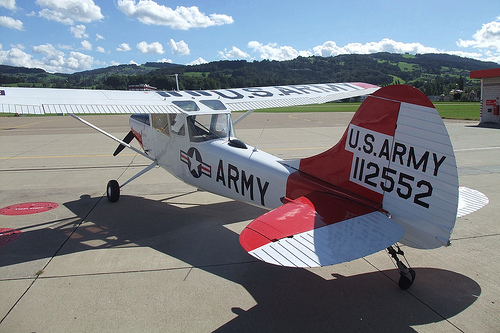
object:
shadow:
[0, 194, 481, 333]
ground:
[0, 114, 499, 333]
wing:
[0, 82, 381, 114]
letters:
[216, 159, 227, 187]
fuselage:
[128, 113, 320, 210]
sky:
[0, 0, 500, 74]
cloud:
[23, 0, 105, 26]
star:
[189, 150, 202, 177]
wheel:
[399, 270, 416, 290]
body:
[143, 122, 302, 211]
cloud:
[0, 15, 27, 31]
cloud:
[0, 0, 18, 11]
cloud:
[116, 43, 131, 52]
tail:
[277, 85, 460, 246]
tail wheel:
[399, 270, 416, 290]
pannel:
[239, 190, 406, 268]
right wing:
[189, 73, 383, 112]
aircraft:
[94, 85, 464, 285]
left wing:
[0, 87, 181, 115]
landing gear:
[120, 161, 157, 187]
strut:
[68, 113, 157, 161]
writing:
[349, 128, 447, 208]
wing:
[238, 191, 405, 267]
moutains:
[0, 52, 500, 87]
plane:
[0, 81, 490, 289]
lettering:
[364, 161, 380, 187]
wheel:
[107, 180, 120, 203]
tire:
[398, 270, 416, 290]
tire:
[107, 180, 120, 203]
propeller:
[113, 130, 135, 156]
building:
[470, 66, 500, 128]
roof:
[470, 68, 499, 79]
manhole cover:
[0, 202, 59, 216]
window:
[187, 113, 235, 142]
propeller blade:
[113, 130, 135, 156]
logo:
[180, 147, 212, 179]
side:
[128, 114, 318, 210]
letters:
[406, 146, 429, 173]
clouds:
[112, 0, 234, 30]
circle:
[1, 202, 59, 216]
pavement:
[0, 110, 499, 332]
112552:
[352, 157, 432, 209]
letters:
[380, 166, 397, 193]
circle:
[186, 146, 202, 178]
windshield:
[186, 113, 234, 143]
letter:
[349, 128, 360, 148]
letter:
[363, 133, 375, 154]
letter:
[378, 139, 389, 161]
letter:
[392, 142, 407, 165]